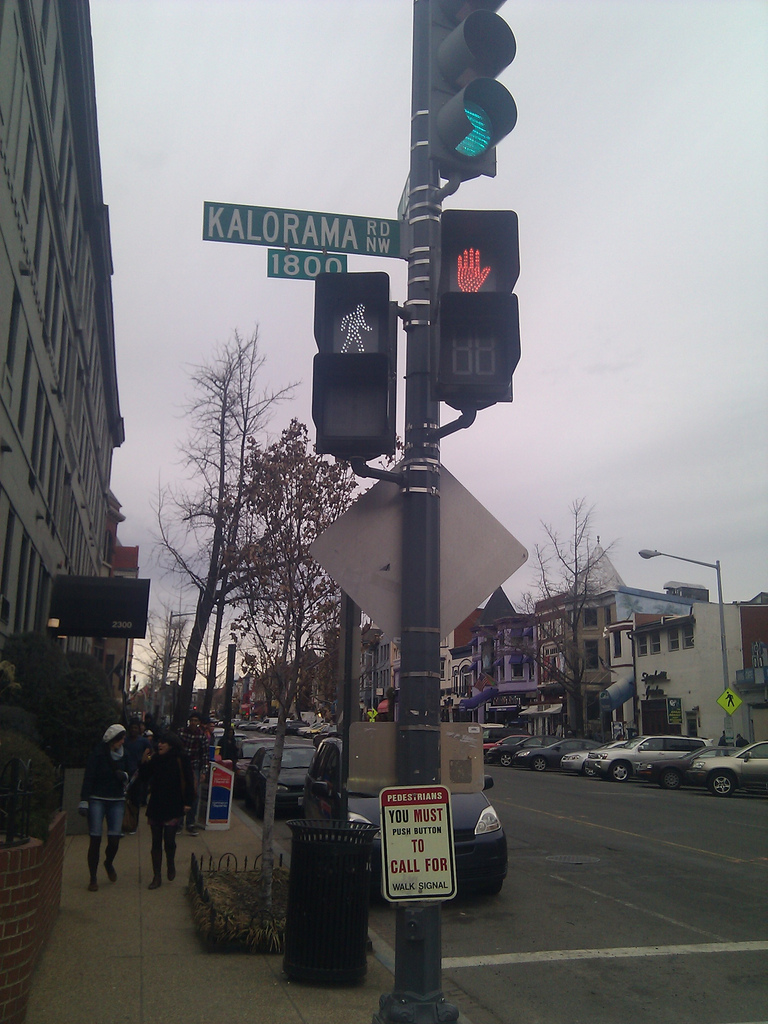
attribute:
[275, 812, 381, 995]
garbage can — black, wrought iron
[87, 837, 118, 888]
boots — black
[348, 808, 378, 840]
headlight — clear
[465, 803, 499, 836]
headlight — clear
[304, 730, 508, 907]
car — blue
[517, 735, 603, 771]
car — blue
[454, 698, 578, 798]
car — parked, red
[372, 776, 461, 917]
sign — red, white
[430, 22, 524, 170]
traffic light — green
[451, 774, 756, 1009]
road — dark grey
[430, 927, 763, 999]
line — white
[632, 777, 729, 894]
lines — yellow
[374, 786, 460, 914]
sign — white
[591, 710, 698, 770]
suv — silver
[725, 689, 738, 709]
person — black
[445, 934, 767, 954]
line — white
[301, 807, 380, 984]
trashcan — black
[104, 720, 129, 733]
hat — white, knit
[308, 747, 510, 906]
van — black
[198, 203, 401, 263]
street sign — green, white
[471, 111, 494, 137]
light — green, lit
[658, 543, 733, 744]
pole — silver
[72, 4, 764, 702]
skies — Large 